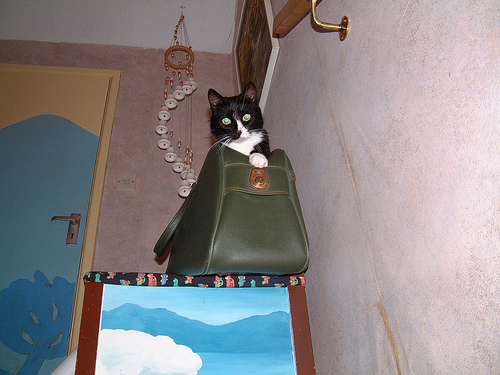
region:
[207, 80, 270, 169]
black and white cat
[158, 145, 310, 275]
green purse with metal attachment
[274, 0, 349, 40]
gold fixture on wall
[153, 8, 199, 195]
wind chime hanging from ceiling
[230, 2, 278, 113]
picture with white frame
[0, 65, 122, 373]
blue and white door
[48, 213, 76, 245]
silver metal doorknob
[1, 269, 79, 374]
blue tree painted on door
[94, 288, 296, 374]
mountains and cloud painted on box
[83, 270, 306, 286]
black fabric with cars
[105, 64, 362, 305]
Cat in a bag.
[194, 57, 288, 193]
Black and white cat in the bag.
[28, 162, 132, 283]
Handle on the door.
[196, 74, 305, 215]
White foot of the cat.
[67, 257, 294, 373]
Clouds in a picture.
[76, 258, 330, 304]
Blanket on the table.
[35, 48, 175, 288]
Door on the wall.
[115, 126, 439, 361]
Green bag with a cat.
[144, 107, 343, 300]
Green bag with grommet.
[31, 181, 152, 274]
Silver handle on the door.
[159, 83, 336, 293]
cat in a green purse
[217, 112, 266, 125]
cat's bright green eyes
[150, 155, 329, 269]
dark green hand bag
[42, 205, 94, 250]
shiny metal door handle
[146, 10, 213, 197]
brown and white wind chime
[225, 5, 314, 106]
framed picture hanging on wall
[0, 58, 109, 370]
painted door and frame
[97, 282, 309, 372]
picture of scenery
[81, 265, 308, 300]
patterned fabric under purse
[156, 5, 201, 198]
a wind chime hanging from a ceiling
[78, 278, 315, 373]
a framed painting propped on a wall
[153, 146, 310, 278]
a green bag with handles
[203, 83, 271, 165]
a black and white cat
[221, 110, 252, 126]
a cat with green eyes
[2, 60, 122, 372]
a door painted yellow and blue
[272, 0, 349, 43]
a golden lamp on the wall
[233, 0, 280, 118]
a white frame on the wall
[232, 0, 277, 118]
a framed painting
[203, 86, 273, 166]
a cat coming out of a green bag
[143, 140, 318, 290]
Green purse with cat on it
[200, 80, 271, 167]
Cat on backpack with glary eyes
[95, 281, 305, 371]
Cloud, mountain and water picture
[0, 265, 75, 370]
Blue tree painted on door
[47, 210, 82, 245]
Push down door handle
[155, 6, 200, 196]
Spinning object in ceiling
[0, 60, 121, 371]
Yellow door posts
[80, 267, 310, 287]
Black blanket with red and blue animals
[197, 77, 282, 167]
Black cat hiding behind purse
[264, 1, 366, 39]
Metal fixture attached to wall